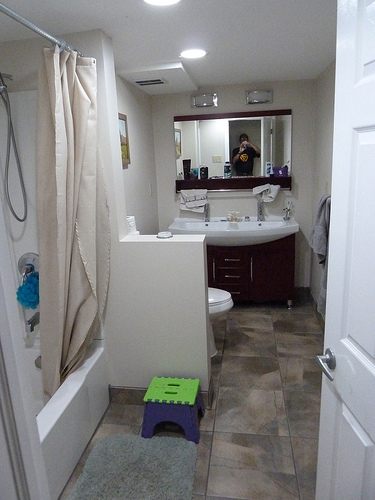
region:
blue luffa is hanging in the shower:
[17, 273, 41, 308]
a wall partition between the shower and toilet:
[113, 267, 218, 358]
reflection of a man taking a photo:
[231, 126, 256, 169]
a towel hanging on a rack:
[312, 191, 329, 261]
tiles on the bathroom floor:
[220, 366, 293, 440]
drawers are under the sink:
[210, 250, 250, 296]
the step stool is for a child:
[141, 377, 198, 440]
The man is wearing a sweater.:
[229, 133, 256, 174]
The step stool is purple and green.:
[142, 370, 206, 443]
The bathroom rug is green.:
[65, 429, 203, 497]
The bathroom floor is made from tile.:
[213, 408, 305, 487]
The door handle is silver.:
[313, 349, 339, 380]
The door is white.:
[321, 388, 374, 493]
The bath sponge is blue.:
[12, 281, 38, 308]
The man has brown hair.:
[237, 132, 249, 144]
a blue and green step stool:
[141, 375, 204, 440]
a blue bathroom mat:
[72, 436, 200, 498]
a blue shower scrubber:
[15, 270, 38, 308]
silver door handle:
[316, 348, 337, 378]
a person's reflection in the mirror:
[231, 134, 259, 174]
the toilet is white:
[205, 287, 233, 356]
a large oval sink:
[186, 219, 284, 228]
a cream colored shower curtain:
[38, 49, 113, 397]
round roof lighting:
[179, 48, 206, 61]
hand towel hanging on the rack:
[179, 188, 207, 210]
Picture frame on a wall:
[117, 113, 130, 167]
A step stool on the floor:
[141, 375, 204, 444]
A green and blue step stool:
[140, 376, 203, 442]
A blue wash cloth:
[15, 273, 39, 308]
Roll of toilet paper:
[125, 215, 136, 231]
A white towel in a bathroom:
[249, 182, 280, 201]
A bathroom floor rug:
[65, 433, 195, 499]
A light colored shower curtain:
[38, 46, 111, 402]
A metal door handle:
[315, 346, 336, 380]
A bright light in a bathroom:
[180, 47, 205, 58]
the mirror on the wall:
[154, 108, 307, 191]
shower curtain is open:
[36, 42, 102, 365]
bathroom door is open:
[305, 0, 370, 495]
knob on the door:
[315, 341, 341, 376]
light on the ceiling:
[171, 43, 211, 63]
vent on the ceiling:
[135, 64, 167, 98]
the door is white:
[316, 0, 373, 499]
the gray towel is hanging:
[298, 193, 331, 316]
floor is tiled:
[224, 358, 308, 484]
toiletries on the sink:
[211, 209, 246, 221]